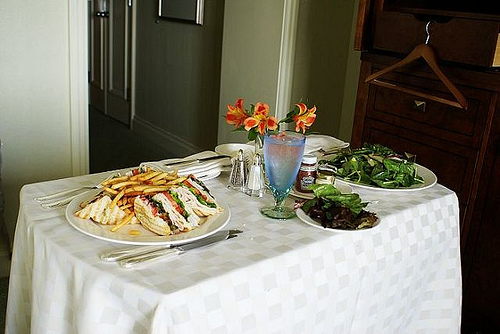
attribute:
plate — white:
[66, 173, 236, 236]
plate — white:
[336, 144, 439, 196]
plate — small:
[301, 187, 382, 235]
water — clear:
[274, 141, 295, 189]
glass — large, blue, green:
[260, 126, 304, 226]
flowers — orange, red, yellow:
[226, 91, 309, 137]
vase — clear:
[253, 134, 275, 170]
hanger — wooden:
[361, 33, 480, 120]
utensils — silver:
[38, 168, 126, 193]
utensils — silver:
[102, 226, 250, 254]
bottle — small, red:
[296, 153, 317, 196]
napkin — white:
[142, 148, 232, 176]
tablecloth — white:
[83, 271, 471, 328]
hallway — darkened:
[88, 7, 204, 138]